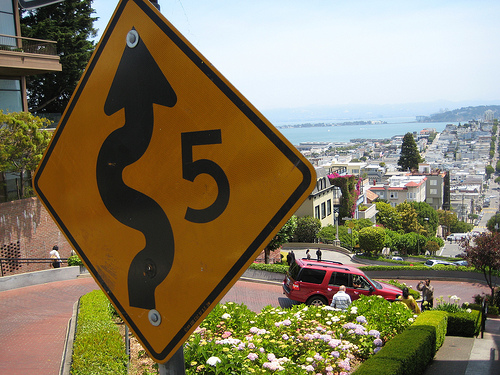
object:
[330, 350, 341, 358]
flowers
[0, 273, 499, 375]
road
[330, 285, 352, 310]
man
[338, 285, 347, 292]
bald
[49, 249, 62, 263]
shirt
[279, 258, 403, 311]
suv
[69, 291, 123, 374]
grass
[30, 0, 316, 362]
sign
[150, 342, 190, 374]
post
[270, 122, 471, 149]
ocean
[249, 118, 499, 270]
city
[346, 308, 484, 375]
hedges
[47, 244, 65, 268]
woman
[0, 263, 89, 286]
sidewalk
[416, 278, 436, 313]
person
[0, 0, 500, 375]
picture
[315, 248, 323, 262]
people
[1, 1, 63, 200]
building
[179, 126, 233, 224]
number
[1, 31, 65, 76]
balcony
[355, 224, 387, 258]
trees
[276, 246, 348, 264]
sidewalk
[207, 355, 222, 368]
flower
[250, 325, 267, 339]
flower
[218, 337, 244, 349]
flower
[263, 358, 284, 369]
flower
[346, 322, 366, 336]
flower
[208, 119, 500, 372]
field